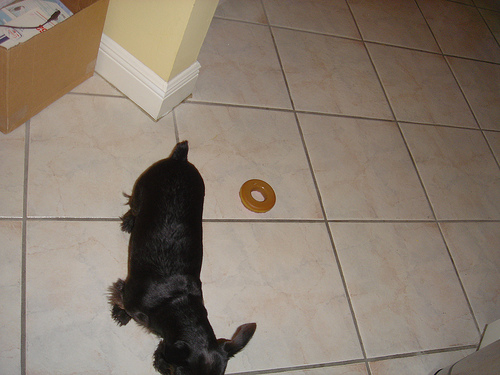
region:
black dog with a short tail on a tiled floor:
[109, 139, 259, 371]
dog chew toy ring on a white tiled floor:
[238, 178, 276, 212]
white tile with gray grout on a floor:
[292, 108, 437, 224]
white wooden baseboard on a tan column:
[92, 31, 202, 122]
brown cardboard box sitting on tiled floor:
[1, 0, 113, 134]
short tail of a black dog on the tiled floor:
[171, 139, 189, 163]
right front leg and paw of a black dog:
[105, 278, 132, 330]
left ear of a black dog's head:
[215, 322, 256, 361]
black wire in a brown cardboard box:
[0, 8, 61, 30]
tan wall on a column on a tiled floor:
[96, 2, 221, 137]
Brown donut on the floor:
[230, 171, 288, 217]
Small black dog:
[100, 131, 261, 373]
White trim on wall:
[97, 35, 222, 130]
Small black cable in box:
[0, 8, 68, 33]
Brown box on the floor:
[2, 0, 112, 147]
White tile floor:
[266, 17, 401, 132]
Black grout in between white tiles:
[289, 106, 340, 228]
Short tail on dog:
[153, 130, 205, 175]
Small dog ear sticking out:
[213, 314, 270, 361]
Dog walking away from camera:
[92, 132, 262, 372]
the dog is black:
[95, 103, 232, 374]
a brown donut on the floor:
[205, 133, 305, 249]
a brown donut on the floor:
[223, 164, 293, 235]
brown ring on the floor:
[228, 157, 279, 226]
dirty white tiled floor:
[328, 14, 468, 277]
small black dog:
[97, 140, 264, 370]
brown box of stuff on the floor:
[2, 0, 107, 125]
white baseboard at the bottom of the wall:
[94, 45, 211, 125]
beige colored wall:
[131, 5, 196, 60]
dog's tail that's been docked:
[161, 131, 193, 162]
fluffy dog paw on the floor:
[110, 283, 130, 333]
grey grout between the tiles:
[16, 215, 37, 365]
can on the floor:
[428, 331, 497, 371]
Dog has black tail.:
[170, 140, 193, 162]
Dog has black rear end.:
[157, 160, 205, 196]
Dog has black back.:
[139, 211, 214, 289]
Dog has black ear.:
[223, 305, 255, 359]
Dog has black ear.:
[156, 330, 184, 358]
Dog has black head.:
[187, 343, 234, 370]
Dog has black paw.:
[106, 280, 132, 331]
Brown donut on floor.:
[241, 166, 287, 229]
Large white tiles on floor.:
[323, 197, 491, 366]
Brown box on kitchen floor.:
[10, 35, 120, 107]